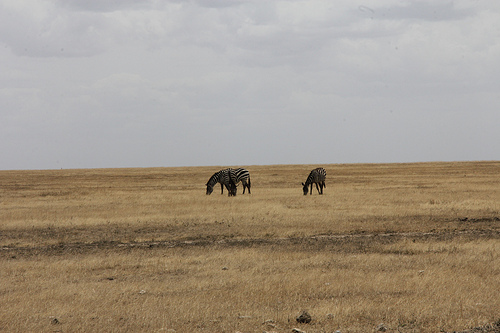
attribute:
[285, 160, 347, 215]
zebra — eating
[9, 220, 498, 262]
dirt — patch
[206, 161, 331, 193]
zebras — grazing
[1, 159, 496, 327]
grass — BROWN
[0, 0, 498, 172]
sky — cloudy, dark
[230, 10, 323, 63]
cloud — dark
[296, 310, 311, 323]
rock — large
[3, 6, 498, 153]
sky — blue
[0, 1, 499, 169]
clouds — dark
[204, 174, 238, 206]
zebra — gathered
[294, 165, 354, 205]
zebra — eating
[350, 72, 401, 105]
gray cloud — dark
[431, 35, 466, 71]
gray cloud — dark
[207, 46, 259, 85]
gray cloud — dark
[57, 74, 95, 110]
gray cloud — dark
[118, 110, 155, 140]
gray cloud — dark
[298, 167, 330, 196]
zebra — white, black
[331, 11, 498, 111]
grey clouds — dark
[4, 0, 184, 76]
grey clouds — dark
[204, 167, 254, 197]
zebra — eating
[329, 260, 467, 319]
grass — dry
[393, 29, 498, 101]
sky — grey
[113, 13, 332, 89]
clouds — gray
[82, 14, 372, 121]
clouds — Dark grey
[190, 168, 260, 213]
zebra — feeding